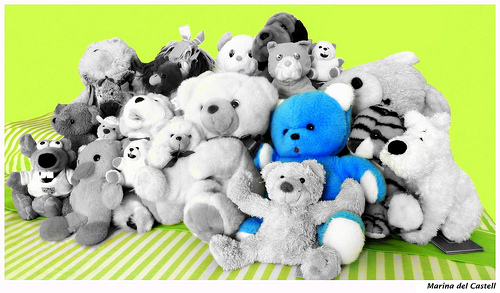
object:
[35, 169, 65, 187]
big teeth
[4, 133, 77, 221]
stuffed animal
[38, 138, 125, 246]
stuffed animals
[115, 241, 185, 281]
stripes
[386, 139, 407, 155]
dog nose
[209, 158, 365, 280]
bear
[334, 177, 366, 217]
hands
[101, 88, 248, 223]
monochromatic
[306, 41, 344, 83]
stuffed animal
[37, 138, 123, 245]
stuffed animal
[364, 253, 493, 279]
stripes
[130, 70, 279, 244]
animals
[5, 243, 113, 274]
bed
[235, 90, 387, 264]
bear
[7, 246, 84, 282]
stripes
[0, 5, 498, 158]
green background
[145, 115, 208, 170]
bears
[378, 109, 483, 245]
dog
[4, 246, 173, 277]
ground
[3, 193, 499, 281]
floor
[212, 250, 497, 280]
ground